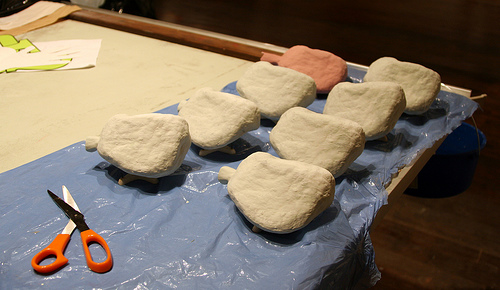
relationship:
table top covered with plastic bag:
[0, 5, 470, 286] [0, 61, 478, 289]